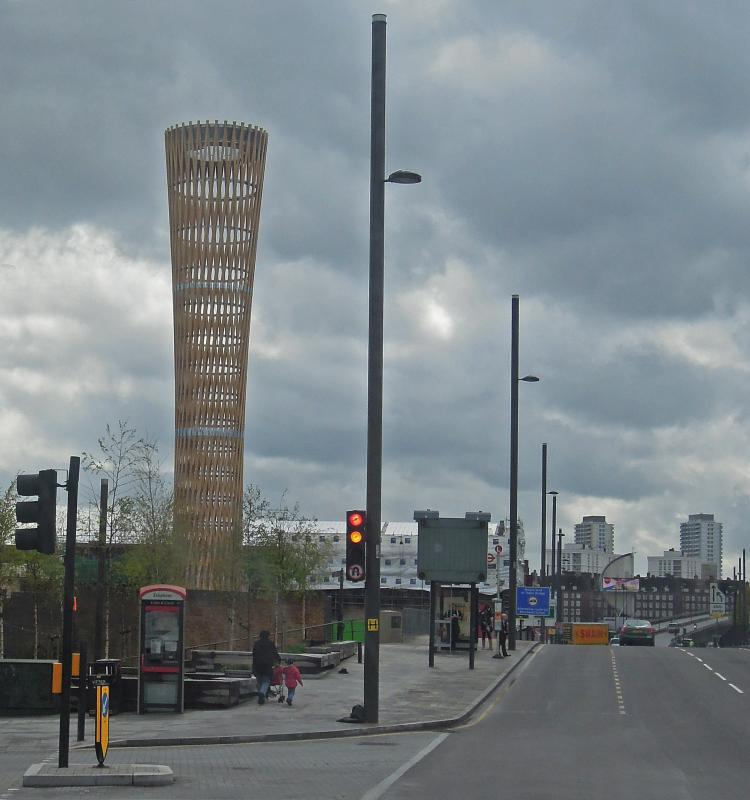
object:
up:
[492, 597, 535, 676]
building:
[0, 493, 750, 714]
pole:
[324, 0, 422, 731]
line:
[607, 638, 632, 720]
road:
[0, 599, 750, 798]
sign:
[509, 579, 559, 623]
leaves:
[274, 543, 286, 559]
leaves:
[127, 553, 143, 569]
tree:
[112, 388, 206, 617]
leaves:
[143, 505, 156, 519]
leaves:
[279, 542, 291, 555]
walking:
[249, 679, 285, 756]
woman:
[241, 623, 286, 708]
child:
[278, 644, 305, 721]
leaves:
[125, 548, 141, 565]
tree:
[0, 442, 85, 680]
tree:
[235, 469, 329, 669]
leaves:
[251, 539, 269, 553]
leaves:
[258, 542, 275, 558]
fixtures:
[357, 144, 466, 224]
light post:
[499, 281, 526, 652]